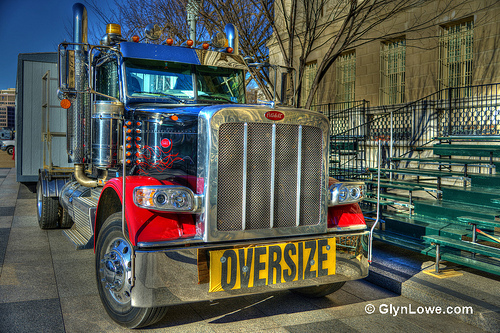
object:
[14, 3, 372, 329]
truck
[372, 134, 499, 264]
bleachers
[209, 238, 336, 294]
sign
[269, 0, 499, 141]
building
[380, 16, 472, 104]
windows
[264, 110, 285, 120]
logo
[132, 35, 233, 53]
lights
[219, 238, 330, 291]
writing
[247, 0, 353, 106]
tree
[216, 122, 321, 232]
grill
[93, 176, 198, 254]
cover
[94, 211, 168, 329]
tire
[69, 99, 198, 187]
diesel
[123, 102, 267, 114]
hood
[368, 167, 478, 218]
benches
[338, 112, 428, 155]
railing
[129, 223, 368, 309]
bumper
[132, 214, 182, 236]
paint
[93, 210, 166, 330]
wheel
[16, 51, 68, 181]
trailer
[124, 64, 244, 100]
windshield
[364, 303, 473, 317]
name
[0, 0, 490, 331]
picture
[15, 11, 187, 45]
sky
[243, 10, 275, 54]
branches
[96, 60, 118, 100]
window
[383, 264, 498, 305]
sidewalk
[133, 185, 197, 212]
headlight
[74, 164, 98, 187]
muffler